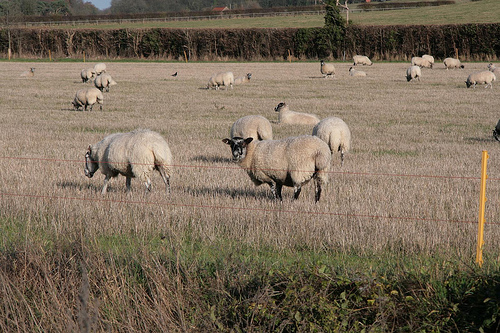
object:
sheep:
[465, 70, 497, 89]